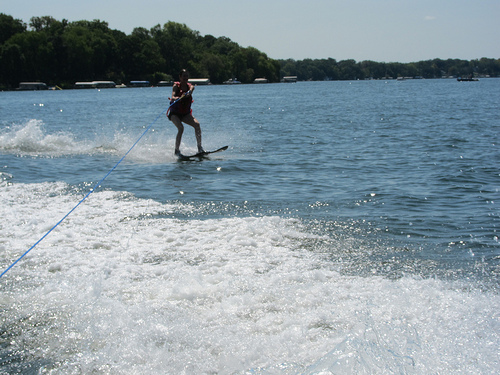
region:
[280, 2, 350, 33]
this is the sky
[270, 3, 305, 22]
the sky is blue in color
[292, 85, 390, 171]
this is the water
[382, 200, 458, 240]
the water has some ripples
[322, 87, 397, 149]
the water is clear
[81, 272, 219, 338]
the water is white in color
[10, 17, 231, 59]
these are some trees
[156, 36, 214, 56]
the leaves are green in color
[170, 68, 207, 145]
this is a person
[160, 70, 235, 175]
the person is surfing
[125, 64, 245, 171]
wakeboarder during daytime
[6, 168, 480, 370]
wake in lake caused by boat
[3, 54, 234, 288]
blue tether cord for wakeboarding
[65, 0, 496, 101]
row of trees alongside lake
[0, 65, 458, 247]
view from boat pulling wakeboarder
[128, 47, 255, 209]
female recreational athlete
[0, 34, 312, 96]
row of docks alongside lake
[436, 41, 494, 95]
boat sitting in lake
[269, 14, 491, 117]
lake, woods, and sky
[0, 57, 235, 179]
wake caused by wakeboarder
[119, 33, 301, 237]
a woman water skiing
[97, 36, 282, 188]
a woman on skies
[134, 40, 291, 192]
a woman standing on skies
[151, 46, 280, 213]
a woman standing on water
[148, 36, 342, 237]
a woman skiing on the body of water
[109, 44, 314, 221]
a skier on the water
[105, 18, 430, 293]
a skier riding on the water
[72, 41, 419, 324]
a skier being pulled on the water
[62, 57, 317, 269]
a skier holding a blue rope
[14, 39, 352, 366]
a woman holding a blue rope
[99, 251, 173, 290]
white waves crashing to the shore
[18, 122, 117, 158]
waves splashing in the water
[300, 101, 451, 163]
calm blue water in the lake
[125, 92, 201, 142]
woman pulling blue rope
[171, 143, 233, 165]
water skis on woman's foot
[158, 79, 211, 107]
woman wearing red vest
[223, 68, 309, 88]
houses dotting the shore line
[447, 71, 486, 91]
black boat in the water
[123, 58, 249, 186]
woman water skiing on skis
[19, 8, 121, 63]
green trees towering over the houses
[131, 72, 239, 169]
A person is water skiing.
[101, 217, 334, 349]
White foam in the water.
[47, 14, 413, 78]
Trees on the side of the ocean.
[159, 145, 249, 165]
Person wearing water skis.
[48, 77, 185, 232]
Person pulling blue rope.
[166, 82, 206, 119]
The person is wearing a life jacket.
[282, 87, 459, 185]
The water is blue.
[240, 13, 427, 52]
The sky is overcasted.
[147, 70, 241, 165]
The person is wet.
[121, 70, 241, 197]
The person is standing in the water.